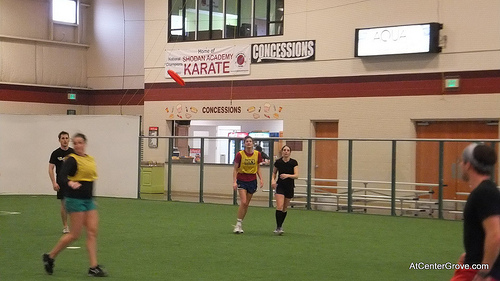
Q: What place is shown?
A: It is a gym.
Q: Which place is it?
A: It is a gym.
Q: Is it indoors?
A: Yes, it is indoors.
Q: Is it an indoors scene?
A: Yes, it is indoors.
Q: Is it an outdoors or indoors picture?
A: It is indoors.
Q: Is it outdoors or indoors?
A: It is indoors.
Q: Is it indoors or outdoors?
A: It is indoors.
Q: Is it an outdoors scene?
A: No, it is indoors.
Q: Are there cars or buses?
A: No, there are no cars or buses.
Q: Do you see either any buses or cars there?
A: No, there are no cars or buses.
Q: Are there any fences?
A: Yes, there is a fence.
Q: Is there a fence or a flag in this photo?
A: Yes, there is a fence.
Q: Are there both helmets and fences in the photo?
A: No, there is a fence but no helmets.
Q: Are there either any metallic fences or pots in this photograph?
A: Yes, there is a metal fence.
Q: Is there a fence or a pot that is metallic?
A: Yes, the fence is metallic.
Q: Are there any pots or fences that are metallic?
A: Yes, the fence is metallic.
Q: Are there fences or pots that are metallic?
A: Yes, the fence is metallic.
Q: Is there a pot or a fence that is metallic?
A: Yes, the fence is metallic.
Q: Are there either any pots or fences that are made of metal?
A: Yes, the fence is made of metal.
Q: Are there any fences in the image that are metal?
A: Yes, there is a metal fence.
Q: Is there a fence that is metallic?
A: Yes, there is a fence that is metallic.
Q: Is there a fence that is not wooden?
A: Yes, there is a metallic fence.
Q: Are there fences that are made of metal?
A: Yes, there is a fence that is made of metal.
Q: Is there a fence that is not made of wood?
A: Yes, there is a fence that is made of metal.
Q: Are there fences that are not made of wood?
A: Yes, there is a fence that is made of metal.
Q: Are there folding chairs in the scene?
A: No, there are no folding chairs.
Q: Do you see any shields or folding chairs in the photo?
A: No, there are no folding chairs or shields.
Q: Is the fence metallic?
A: Yes, the fence is metallic.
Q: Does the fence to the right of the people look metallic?
A: Yes, the fence is metallic.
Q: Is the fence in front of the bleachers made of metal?
A: Yes, the fence is made of metal.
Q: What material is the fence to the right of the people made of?
A: The fence is made of metal.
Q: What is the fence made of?
A: The fence is made of metal.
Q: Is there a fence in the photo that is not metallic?
A: No, there is a fence but it is metallic.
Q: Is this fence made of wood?
A: No, the fence is made of metal.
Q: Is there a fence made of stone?
A: No, there is a fence but it is made of metal.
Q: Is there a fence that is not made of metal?
A: No, there is a fence but it is made of metal.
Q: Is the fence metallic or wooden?
A: The fence is metallic.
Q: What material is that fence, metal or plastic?
A: The fence is made of metal.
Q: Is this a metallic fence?
A: Yes, this is a metallic fence.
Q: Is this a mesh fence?
A: No, this is a metallic fence.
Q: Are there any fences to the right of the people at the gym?
A: Yes, there is a fence to the right of the people.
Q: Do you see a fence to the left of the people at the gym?
A: No, the fence is to the right of the people.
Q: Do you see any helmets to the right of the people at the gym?
A: No, there is a fence to the right of the people.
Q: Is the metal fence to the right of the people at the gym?
A: Yes, the fence is to the right of the people.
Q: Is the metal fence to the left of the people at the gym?
A: No, the fence is to the right of the people.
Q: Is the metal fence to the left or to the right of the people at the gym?
A: The fence is to the right of the people.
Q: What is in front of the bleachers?
A: The fence is in front of the bleachers.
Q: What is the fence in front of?
A: The fence is in front of the bleachers.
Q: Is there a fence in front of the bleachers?
A: Yes, there is a fence in front of the bleachers.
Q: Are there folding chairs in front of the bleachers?
A: No, there is a fence in front of the bleachers.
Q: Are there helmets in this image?
A: No, there are no helmets.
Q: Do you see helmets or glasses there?
A: No, there are no helmets or glasses.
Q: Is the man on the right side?
A: Yes, the man is on the right of the image.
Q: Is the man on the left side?
A: No, the man is on the right of the image.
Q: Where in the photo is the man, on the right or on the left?
A: The man is on the right of the image.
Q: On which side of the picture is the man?
A: The man is on the right of the image.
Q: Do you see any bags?
A: No, there are no bags.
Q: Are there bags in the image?
A: No, there are no bags.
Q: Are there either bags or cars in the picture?
A: No, there are no bags or cars.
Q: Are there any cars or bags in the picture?
A: No, there are no bags or cars.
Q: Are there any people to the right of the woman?
A: Yes, there are people to the right of the woman.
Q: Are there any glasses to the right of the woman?
A: No, there are people to the right of the woman.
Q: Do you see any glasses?
A: No, there are no glasses.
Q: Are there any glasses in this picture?
A: No, there are no glasses.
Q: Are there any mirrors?
A: No, there are no mirrors.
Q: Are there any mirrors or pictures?
A: No, there are no mirrors or pictures.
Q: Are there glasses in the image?
A: No, there are no glasses.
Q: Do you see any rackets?
A: No, there are no rackets.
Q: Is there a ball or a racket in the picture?
A: No, there are no rackets or balls.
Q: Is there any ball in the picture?
A: No, there are no balls.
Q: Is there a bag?
A: No, there are no bags.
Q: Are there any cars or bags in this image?
A: No, there are no bags or cars.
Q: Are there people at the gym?
A: Yes, there are people at the gym.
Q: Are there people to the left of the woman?
A: Yes, there are people to the left of the woman.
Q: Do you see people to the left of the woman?
A: Yes, there are people to the left of the woman.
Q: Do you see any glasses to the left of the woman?
A: No, there are people to the left of the woman.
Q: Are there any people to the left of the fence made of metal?
A: Yes, there are people to the left of the fence.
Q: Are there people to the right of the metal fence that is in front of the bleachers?
A: No, the people are to the left of the fence.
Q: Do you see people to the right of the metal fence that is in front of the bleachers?
A: No, the people are to the left of the fence.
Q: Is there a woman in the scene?
A: Yes, there is a woman.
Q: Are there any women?
A: Yes, there is a woman.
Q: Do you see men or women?
A: Yes, there is a woman.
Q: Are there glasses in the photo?
A: No, there are no glasses.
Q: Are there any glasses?
A: No, there are no glasses.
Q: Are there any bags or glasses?
A: No, there are no glasses or bags.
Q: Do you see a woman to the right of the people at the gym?
A: Yes, there is a woman to the right of the people.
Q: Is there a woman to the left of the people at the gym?
A: No, the woman is to the right of the people.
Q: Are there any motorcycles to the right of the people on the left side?
A: No, there is a woman to the right of the people.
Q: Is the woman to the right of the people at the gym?
A: Yes, the woman is to the right of the people.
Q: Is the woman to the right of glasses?
A: No, the woman is to the right of the people.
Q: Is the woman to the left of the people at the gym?
A: No, the woman is to the right of the people.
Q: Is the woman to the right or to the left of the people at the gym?
A: The woman is to the right of the people.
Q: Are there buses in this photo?
A: No, there are no buses.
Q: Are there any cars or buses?
A: No, there are no buses or cars.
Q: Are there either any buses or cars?
A: No, there are no buses or cars.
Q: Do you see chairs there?
A: No, there are no chairs.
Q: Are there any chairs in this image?
A: No, there are no chairs.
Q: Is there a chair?
A: No, there are no chairs.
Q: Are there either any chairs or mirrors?
A: No, there are no chairs or mirrors.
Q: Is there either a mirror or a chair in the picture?
A: No, there are no chairs or mirrors.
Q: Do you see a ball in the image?
A: No, there are no balls.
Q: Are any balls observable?
A: No, there are no balls.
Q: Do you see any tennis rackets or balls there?
A: No, there are no balls or tennis rackets.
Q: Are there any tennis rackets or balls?
A: No, there are no balls or tennis rackets.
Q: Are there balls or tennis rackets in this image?
A: No, there are no balls or tennis rackets.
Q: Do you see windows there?
A: Yes, there is a window.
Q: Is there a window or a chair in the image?
A: Yes, there is a window.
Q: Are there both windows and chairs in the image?
A: No, there is a window but no chairs.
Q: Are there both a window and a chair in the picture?
A: No, there is a window but no chairs.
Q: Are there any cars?
A: No, there are no cars.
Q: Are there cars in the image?
A: No, there are no cars.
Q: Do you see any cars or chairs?
A: No, there are no cars or chairs.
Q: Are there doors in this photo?
A: Yes, there is a door.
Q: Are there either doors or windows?
A: Yes, there is a door.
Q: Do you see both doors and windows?
A: Yes, there are both a door and a window.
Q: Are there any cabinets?
A: No, there are no cabinets.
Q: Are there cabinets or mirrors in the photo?
A: No, there are no cabinets or mirrors.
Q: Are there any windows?
A: Yes, there is a window.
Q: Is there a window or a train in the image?
A: Yes, there is a window.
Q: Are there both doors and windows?
A: Yes, there are both a window and a door.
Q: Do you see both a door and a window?
A: Yes, there are both a window and a door.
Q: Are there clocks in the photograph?
A: No, there are no clocks.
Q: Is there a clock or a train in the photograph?
A: No, there are no clocks or trains.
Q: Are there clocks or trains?
A: No, there are no clocks or trains.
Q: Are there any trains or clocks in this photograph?
A: No, there are no clocks or trains.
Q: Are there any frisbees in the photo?
A: Yes, there is a frisbee.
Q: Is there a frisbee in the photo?
A: Yes, there is a frisbee.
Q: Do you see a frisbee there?
A: Yes, there is a frisbee.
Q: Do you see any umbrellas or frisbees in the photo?
A: Yes, there is a frisbee.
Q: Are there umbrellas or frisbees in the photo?
A: Yes, there is a frisbee.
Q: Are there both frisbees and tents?
A: No, there is a frisbee but no tents.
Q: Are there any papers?
A: No, there are no papers.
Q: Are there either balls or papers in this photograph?
A: No, there are no papers or balls.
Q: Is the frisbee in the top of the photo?
A: Yes, the frisbee is in the top of the image.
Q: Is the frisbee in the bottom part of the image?
A: No, the frisbee is in the top of the image.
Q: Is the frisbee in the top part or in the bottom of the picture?
A: The frisbee is in the top of the image.